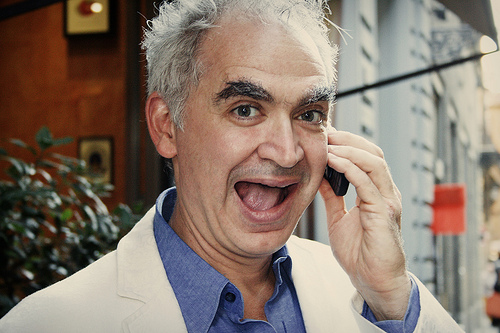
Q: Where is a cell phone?
A: In man's left hand.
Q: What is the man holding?
A: A phone.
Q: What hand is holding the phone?
A: The man's left hand.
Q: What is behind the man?
A: A building.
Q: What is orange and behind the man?
A: A sign.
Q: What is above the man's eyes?
A: Eyebrows.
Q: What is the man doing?
A: Talking on the phone.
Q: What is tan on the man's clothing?
A: The jacket.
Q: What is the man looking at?
A: The camera.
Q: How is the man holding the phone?
A: With his left hand.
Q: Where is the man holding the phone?
A: To his ear.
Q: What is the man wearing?
A: Shirt and jacket.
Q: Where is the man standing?
A: In front of buildings.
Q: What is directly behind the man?
A: Green bushes.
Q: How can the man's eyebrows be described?
A: Bushy.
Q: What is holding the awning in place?
A: A black metal pole.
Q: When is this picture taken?
A: Daytime.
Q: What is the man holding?
A: A Phone.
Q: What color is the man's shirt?
A: Blue.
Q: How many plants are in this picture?
A: One.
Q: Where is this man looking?
A: At the camera.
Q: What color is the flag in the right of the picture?
A: Red.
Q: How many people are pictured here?
A: One.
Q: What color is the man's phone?
A: Black.